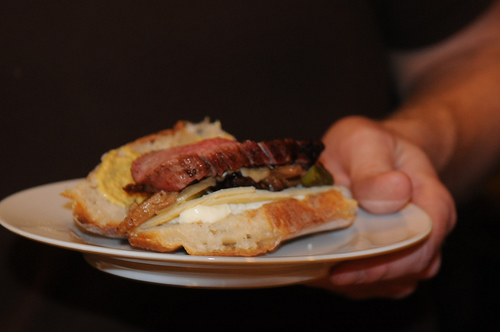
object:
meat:
[129, 131, 295, 193]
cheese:
[99, 154, 127, 205]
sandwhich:
[57, 119, 357, 257]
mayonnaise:
[180, 206, 228, 221]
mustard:
[115, 151, 135, 166]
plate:
[0, 176, 431, 292]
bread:
[57, 182, 123, 235]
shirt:
[388, 4, 499, 101]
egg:
[249, 183, 273, 197]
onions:
[177, 178, 211, 204]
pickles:
[299, 159, 322, 188]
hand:
[320, 116, 461, 300]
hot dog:
[130, 135, 288, 192]